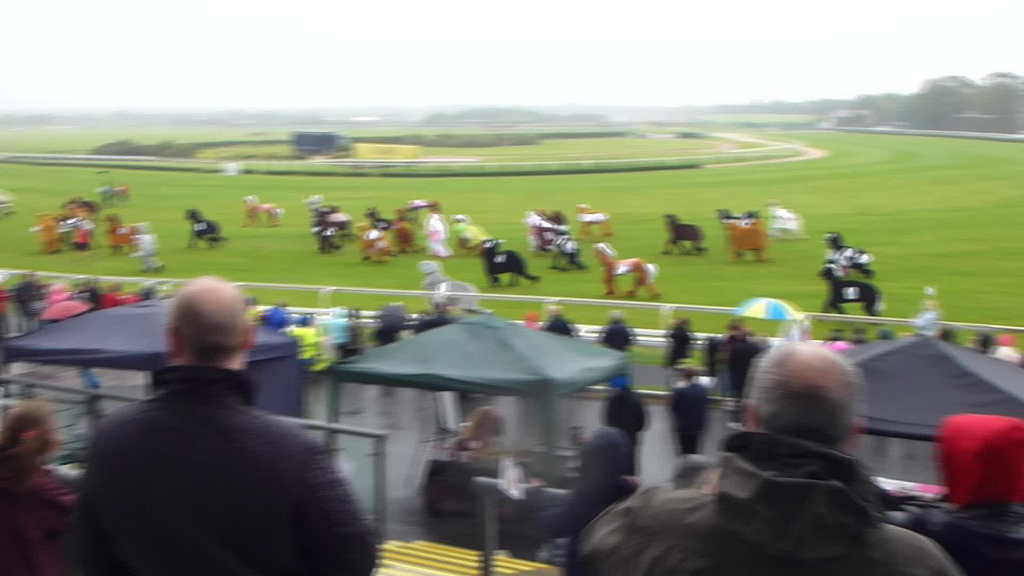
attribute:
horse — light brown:
[261, 184, 326, 258]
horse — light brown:
[326, 214, 437, 286]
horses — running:
[125, 178, 739, 285]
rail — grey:
[287, 415, 409, 498]